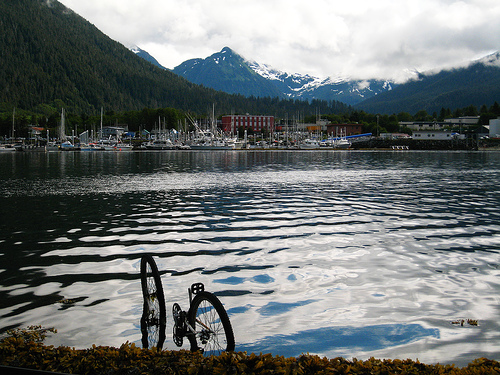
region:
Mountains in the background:
[120, 31, 498, 123]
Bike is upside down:
[125, 245, 250, 353]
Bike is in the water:
[114, 244, 251, 350]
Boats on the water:
[36, 109, 356, 156]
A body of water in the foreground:
[1, 123, 498, 367]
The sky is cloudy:
[69, 4, 499, 88]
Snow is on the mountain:
[231, 47, 378, 102]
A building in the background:
[217, 107, 282, 141]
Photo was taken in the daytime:
[3, 1, 498, 374]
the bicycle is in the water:
[118, 238, 260, 374]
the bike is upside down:
[95, 226, 272, 363]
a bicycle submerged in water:
[115, 235, 260, 360]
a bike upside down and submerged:
[96, 227, 264, 363]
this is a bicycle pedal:
[180, 268, 210, 295]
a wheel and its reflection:
[113, 230, 174, 361]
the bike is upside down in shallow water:
[92, 215, 252, 355]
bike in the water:
[131, 249, 262, 344]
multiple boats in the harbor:
[65, 121, 405, 151]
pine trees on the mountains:
[65, 33, 346, 141]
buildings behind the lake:
[404, 122, 487, 145]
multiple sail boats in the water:
[60, 113, 142, 148]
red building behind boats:
[224, 114, 287, 131]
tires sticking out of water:
[133, 253, 278, 365]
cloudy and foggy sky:
[191, 5, 434, 110]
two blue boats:
[61, 136, 96, 148]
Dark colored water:
[4, 129, 496, 372]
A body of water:
[1, 149, 494, 364]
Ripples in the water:
[6, 169, 498, 358]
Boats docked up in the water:
[4, 112, 391, 160]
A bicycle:
[120, 246, 247, 366]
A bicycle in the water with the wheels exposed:
[127, 242, 242, 360]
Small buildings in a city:
[22, 98, 493, 158]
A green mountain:
[0, 0, 361, 139]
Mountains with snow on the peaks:
[136, 39, 496, 109]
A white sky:
[59, 1, 499, 92]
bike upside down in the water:
[99, 236, 242, 373]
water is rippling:
[226, 174, 377, 310]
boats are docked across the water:
[59, 108, 268, 155]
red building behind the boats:
[216, 110, 275, 131]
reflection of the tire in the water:
[136, 312, 164, 346]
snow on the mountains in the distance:
[266, 62, 317, 85]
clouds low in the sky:
[241, 10, 366, 57]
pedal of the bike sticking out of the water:
[188, 277, 205, 301]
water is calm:
[102, 160, 409, 207]